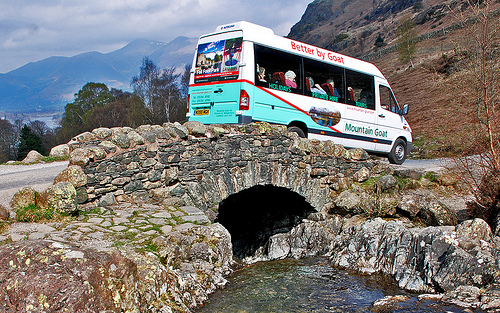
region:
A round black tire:
[385, 130, 410, 166]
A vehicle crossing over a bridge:
[40, 15, 426, 215]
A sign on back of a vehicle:
[187, 31, 242, 88]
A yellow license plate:
[186, 100, 208, 117]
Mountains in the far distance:
[0, 31, 200, 116]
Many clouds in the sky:
[0, 0, 315, 77]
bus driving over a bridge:
[173, 15, 423, 152]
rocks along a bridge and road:
[129, 140, 188, 172]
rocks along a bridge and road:
[240, 134, 281, 156]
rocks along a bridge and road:
[338, 158, 393, 193]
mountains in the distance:
[17, 22, 217, 102]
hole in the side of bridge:
[203, 185, 310, 246]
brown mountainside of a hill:
[408, 33, 483, 108]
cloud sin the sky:
[26, 15, 85, 53]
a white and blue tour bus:
[185, 21, 412, 161]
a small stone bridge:
[61, 124, 366, 260]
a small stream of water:
[191, 256, 488, 311]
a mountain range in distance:
[0, 32, 200, 111]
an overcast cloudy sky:
[1, 0, 310, 74]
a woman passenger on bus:
[283, 68, 298, 88]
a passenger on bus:
[308, 76, 326, 94]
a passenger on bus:
[257, 66, 266, 83]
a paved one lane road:
[0, 160, 70, 203]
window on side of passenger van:
[343, 67, 376, 111]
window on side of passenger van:
[303, 56, 345, 103]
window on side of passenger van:
[252, 42, 304, 95]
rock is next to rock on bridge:
[141, 156, 161, 169]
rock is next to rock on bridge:
[163, 153, 180, 164]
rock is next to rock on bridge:
[240, 147, 252, 160]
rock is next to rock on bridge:
[112, 176, 133, 185]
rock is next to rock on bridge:
[94, 186, 116, 195]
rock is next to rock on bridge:
[353, 163, 369, 184]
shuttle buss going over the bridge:
[184, 20, 414, 165]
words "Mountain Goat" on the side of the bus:
[343, 121, 389, 138]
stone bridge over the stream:
[50, 120, 370, 215]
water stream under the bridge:
[191, 250, 485, 311]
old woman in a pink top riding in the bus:
[283, 69, 297, 90]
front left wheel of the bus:
[387, 135, 409, 165]